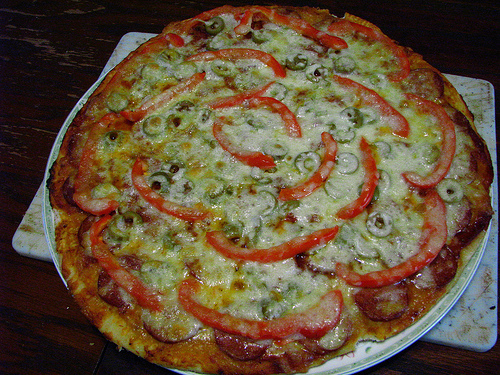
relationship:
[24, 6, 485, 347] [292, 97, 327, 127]
pizza covered in cheese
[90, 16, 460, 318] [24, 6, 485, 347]
olive on pizza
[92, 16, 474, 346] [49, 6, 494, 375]
cheese melted on top of pizza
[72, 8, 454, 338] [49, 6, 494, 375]
bell pepper lying on top of pizza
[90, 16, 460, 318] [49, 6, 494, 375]
olive lying on top of pizza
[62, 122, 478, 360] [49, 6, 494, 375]
pepperoni lying on top of pizza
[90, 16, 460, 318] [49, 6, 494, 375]
olive lying on pizza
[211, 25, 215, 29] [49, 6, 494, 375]
black olive lying on top of pizza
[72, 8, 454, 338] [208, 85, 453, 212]
bell pepper lying on top of pizza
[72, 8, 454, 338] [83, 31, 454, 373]
bell pepper on pizza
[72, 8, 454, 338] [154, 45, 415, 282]
bell pepper on pizza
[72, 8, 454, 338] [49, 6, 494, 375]
bell pepper on pizza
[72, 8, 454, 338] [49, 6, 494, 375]
bell pepper on top of pizza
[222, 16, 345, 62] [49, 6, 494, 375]
bell pepper on top of pizza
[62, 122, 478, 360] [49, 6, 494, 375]
pepperoni on pizza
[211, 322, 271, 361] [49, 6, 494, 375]
pepperoni on pizza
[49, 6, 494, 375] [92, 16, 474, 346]
pizza covered in cheese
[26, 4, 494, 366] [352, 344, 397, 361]
plate has plate trim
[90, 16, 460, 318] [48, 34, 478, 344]
olive on pizza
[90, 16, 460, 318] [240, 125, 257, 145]
olive on cheese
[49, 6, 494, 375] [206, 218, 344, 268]
pizza has tomato slice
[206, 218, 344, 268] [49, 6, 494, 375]
tomato slice in pizza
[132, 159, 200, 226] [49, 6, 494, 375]
tomato slice in pizza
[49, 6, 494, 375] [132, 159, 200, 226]
pizza has tomato slice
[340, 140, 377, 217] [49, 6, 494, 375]
tomato slice in pizza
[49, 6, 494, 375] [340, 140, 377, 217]
pizza has tomato slice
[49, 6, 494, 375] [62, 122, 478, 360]
pizza has pepperoni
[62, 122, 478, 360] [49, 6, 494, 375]
pepperoni in pizza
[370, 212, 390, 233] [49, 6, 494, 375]
black olive on pizza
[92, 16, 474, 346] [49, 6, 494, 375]
cheese covering pizza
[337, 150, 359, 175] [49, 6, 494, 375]
olive on pizza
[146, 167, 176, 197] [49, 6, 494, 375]
black olive on pizza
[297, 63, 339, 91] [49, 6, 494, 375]
black olive on pizza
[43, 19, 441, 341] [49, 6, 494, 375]
black olive on pizza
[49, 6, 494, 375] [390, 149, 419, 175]
pizza covered in cheese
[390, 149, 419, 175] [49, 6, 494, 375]
cheese covering pizza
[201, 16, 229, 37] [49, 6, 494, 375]
black olive on pizza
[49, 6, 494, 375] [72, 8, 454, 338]
pizza has bell pepper